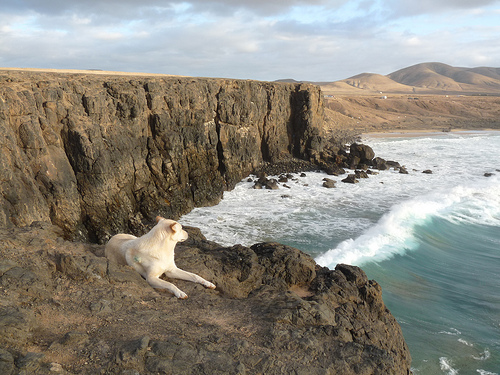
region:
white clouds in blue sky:
[74, 9, 112, 40]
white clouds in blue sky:
[321, 11, 365, 52]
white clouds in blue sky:
[210, 0, 247, 31]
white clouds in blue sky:
[282, 32, 353, 80]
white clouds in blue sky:
[247, 18, 308, 58]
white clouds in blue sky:
[151, 23, 229, 77]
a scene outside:
[12, 13, 496, 373]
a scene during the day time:
[5, 4, 497, 373]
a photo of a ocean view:
[1, 0, 498, 369]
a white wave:
[291, 174, 498, 287]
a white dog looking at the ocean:
[75, 208, 268, 328]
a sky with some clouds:
[3, 0, 472, 89]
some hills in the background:
[259, 44, 497, 105]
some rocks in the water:
[247, 136, 425, 194]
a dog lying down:
[84, 205, 229, 306]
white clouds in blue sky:
[232, 23, 294, 66]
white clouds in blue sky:
[304, 18, 359, 51]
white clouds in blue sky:
[174, 8, 234, 60]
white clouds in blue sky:
[119, 13, 152, 38]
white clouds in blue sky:
[245, 13, 285, 43]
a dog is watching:
[90, 205, 230, 315]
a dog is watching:
[110, 205, 219, 301]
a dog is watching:
[85, 191, 202, 305]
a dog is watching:
[103, 195, 194, 276]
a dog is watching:
[89, 196, 239, 318]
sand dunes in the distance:
[345, 50, 497, 97]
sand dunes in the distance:
[298, 40, 498, 105]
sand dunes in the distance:
[318, 47, 493, 100]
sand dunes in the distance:
[303, 45, 493, 101]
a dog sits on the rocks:
[91, 193, 239, 318]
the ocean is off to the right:
[243, 125, 490, 373]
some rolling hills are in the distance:
[326, 60, 496, 110]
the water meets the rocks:
[255, 150, 414, 197]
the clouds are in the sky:
[13, 5, 483, 81]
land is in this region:
[327, 97, 484, 126]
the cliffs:
[78, 74, 318, 214]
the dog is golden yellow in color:
[88, 208, 237, 310]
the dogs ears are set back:
[153, 208, 181, 240]